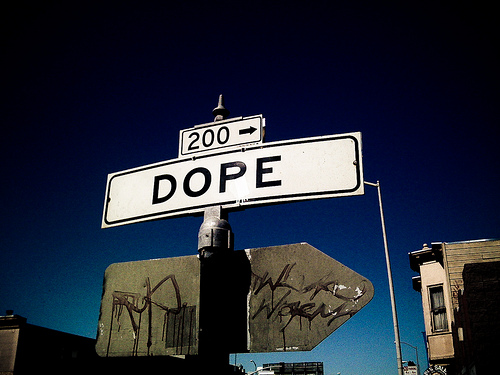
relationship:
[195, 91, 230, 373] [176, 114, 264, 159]
pole with sign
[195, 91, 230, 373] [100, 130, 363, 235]
pole with sign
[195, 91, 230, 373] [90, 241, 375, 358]
pole with sign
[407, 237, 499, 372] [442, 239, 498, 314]
building covered with planks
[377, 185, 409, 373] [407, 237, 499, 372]
lamp pole in front of building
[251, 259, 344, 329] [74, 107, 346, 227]
graffiti on back of sign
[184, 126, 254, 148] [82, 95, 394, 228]
lettering on sign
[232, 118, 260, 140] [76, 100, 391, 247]
arrow on sign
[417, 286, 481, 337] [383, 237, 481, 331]
window on house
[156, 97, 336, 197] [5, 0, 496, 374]
signs set against sky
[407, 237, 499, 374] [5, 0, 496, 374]
building against sky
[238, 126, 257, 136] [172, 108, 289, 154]
arrow on sign